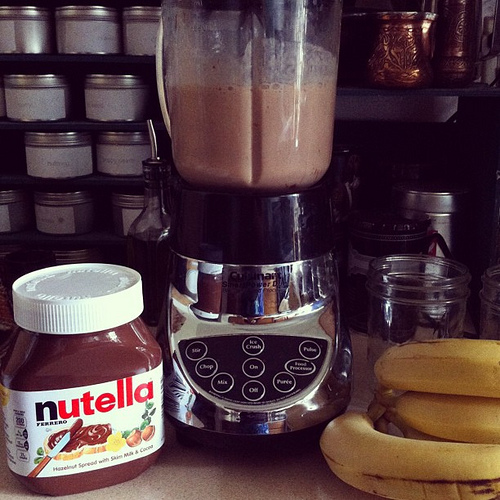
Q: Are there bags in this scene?
A: No, there are no bags.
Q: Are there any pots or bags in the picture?
A: No, there are no bags or pots.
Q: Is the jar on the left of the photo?
A: Yes, the jar is on the left of the image.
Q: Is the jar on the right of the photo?
A: No, the jar is on the left of the image.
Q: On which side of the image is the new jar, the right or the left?
A: The jar is on the left of the image.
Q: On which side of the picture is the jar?
A: The jar is on the left of the image.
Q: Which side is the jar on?
A: The jar is on the left of the image.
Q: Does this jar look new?
A: Yes, the jar is new.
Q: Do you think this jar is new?
A: Yes, the jar is new.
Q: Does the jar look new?
A: Yes, the jar is new.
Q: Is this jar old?
A: No, the jar is new.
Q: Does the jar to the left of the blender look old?
A: No, the jar is new.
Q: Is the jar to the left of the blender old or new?
A: The jar is new.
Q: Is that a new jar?
A: Yes, that is a new jar.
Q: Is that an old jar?
A: No, that is a new jar.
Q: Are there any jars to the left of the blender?
A: Yes, there is a jar to the left of the blender.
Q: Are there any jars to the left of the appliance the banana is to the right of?
A: Yes, there is a jar to the left of the blender.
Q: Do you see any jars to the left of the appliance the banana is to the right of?
A: Yes, there is a jar to the left of the blender.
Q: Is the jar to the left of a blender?
A: Yes, the jar is to the left of a blender.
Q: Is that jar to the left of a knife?
A: No, the jar is to the left of a blender.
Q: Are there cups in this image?
A: No, there are no cups.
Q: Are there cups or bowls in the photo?
A: No, there are no cups or bowls.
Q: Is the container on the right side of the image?
A: No, the container is on the left of the image.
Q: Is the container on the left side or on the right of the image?
A: The container is on the left of the image.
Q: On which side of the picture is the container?
A: The container is on the left of the image.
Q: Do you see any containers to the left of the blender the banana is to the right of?
A: Yes, there is a container to the left of the blender.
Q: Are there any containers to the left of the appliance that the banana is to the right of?
A: Yes, there is a container to the left of the blender.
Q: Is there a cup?
A: No, there are no cups.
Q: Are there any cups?
A: No, there are no cups.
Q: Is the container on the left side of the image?
A: Yes, the container is on the left of the image.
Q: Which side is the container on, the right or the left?
A: The container is on the left of the image.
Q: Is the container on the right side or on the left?
A: The container is on the left of the image.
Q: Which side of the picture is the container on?
A: The container is on the left of the image.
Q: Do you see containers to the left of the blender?
A: Yes, there is a container to the left of the blender.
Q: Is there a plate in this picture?
A: No, there are no plates.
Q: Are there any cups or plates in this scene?
A: No, there are no plates or cups.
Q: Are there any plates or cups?
A: No, there are no plates or cups.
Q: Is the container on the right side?
A: No, the container is on the left of the image.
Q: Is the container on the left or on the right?
A: The container is on the left of the image.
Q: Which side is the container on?
A: The container is on the left of the image.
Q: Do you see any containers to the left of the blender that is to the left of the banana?
A: Yes, there is a container to the left of the blender.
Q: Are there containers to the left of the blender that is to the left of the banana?
A: Yes, there is a container to the left of the blender.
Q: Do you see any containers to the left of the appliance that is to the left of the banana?
A: Yes, there is a container to the left of the blender.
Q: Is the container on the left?
A: Yes, the container is on the left of the image.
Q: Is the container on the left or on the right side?
A: The container is on the left of the image.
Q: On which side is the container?
A: The container is on the left of the image.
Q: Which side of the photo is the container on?
A: The container is on the left of the image.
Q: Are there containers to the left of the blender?
A: Yes, there is a container to the left of the blender.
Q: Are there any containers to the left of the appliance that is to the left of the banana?
A: Yes, there is a container to the left of the blender.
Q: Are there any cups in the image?
A: No, there are no cups.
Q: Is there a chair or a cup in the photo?
A: No, there are no cups or chairs.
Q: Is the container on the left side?
A: Yes, the container is on the left of the image.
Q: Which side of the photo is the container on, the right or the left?
A: The container is on the left of the image.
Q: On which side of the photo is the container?
A: The container is on the left of the image.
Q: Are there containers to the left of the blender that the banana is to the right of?
A: Yes, there is a container to the left of the blender.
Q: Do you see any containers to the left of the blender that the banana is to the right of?
A: Yes, there is a container to the left of the blender.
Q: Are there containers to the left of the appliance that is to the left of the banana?
A: Yes, there is a container to the left of the blender.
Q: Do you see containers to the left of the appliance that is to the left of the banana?
A: Yes, there is a container to the left of the blender.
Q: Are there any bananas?
A: Yes, there is a banana.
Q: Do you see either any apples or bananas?
A: Yes, there is a banana.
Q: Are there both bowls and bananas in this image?
A: No, there is a banana but no bowls.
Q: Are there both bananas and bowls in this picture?
A: No, there is a banana but no bowls.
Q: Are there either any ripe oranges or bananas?
A: Yes, there is a ripe banana.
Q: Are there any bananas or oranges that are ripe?
A: Yes, the banana is ripe.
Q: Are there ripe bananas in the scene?
A: Yes, there is a ripe banana.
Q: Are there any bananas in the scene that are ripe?
A: Yes, there is a banana that is ripe.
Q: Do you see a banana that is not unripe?
A: Yes, there is an ripe banana.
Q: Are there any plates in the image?
A: No, there are no plates.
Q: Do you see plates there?
A: No, there are no plates.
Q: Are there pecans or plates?
A: No, there are no plates or pecans.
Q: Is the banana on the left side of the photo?
A: No, the banana is on the right of the image.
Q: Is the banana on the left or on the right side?
A: The banana is on the right of the image.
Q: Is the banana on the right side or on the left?
A: The banana is on the right of the image.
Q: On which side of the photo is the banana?
A: The banana is on the right of the image.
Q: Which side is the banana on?
A: The banana is on the right of the image.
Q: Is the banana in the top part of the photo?
A: No, the banana is in the bottom of the image.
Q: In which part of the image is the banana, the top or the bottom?
A: The banana is in the bottom of the image.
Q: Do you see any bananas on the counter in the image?
A: Yes, there is a banana on the counter.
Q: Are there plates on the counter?
A: No, there is a banana on the counter.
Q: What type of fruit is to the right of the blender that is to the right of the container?
A: The fruit is a banana.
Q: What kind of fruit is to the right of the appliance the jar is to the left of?
A: The fruit is a banana.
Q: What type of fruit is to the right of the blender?
A: The fruit is a banana.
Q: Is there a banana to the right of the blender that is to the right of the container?
A: Yes, there is a banana to the right of the blender.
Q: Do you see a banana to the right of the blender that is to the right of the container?
A: Yes, there is a banana to the right of the blender.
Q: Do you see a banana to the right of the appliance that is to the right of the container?
A: Yes, there is a banana to the right of the blender.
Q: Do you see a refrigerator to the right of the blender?
A: No, there is a banana to the right of the blender.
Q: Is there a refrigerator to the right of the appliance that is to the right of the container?
A: No, there is a banana to the right of the blender.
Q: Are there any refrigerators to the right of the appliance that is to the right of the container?
A: No, there is a banana to the right of the blender.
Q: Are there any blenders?
A: Yes, there is a blender.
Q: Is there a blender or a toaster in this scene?
A: Yes, there is a blender.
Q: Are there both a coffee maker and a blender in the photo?
A: No, there is a blender but no coffee makers.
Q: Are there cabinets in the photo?
A: No, there are no cabinets.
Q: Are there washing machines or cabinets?
A: No, there are no cabinets or washing machines.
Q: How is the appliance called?
A: The appliance is a blender.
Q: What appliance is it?
A: The appliance is a blender.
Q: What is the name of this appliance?
A: This is a blender.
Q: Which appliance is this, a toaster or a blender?
A: This is a blender.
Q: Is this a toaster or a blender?
A: This is a blender.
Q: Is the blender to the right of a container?
A: Yes, the blender is to the right of a container.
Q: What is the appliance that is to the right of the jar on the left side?
A: The appliance is a blender.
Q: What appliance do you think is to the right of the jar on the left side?
A: The appliance is a blender.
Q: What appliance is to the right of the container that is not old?
A: The appliance is a blender.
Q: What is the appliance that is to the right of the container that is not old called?
A: The appliance is a blender.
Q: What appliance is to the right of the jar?
A: The appliance is a blender.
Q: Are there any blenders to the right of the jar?
A: Yes, there is a blender to the right of the jar.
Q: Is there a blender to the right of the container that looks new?
A: Yes, there is a blender to the right of the jar.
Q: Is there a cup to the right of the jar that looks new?
A: No, there is a blender to the right of the jar.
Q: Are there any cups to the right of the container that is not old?
A: No, there is a blender to the right of the jar.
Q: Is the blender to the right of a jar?
A: Yes, the blender is to the right of a jar.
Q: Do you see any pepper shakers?
A: No, there are no pepper shakers.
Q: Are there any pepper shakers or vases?
A: No, there are no pepper shakers or vases.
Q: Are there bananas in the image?
A: Yes, there is a banana.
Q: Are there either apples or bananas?
A: Yes, there is a banana.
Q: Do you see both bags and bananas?
A: No, there is a banana but no bags.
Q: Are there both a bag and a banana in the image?
A: No, there is a banana but no bags.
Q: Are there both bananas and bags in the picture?
A: No, there is a banana but no bags.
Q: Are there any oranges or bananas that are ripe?
A: Yes, the banana is ripe.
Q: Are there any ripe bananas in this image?
A: Yes, there is a ripe banana.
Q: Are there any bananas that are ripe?
A: Yes, there is a banana that is ripe.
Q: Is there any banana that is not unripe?
A: Yes, there is an ripe banana.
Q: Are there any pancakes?
A: No, there are no pancakes.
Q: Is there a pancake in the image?
A: No, there are no pancakes.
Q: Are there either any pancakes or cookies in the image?
A: No, there are no pancakes or cookies.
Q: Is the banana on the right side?
A: Yes, the banana is on the right of the image.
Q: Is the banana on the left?
A: No, the banana is on the right of the image.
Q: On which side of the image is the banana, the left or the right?
A: The banana is on the right of the image.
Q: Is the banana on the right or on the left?
A: The banana is on the right of the image.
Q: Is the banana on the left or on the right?
A: The banana is on the right of the image.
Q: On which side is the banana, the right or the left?
A: The banana is on the right of the image.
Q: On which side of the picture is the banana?
A: The banana is on the right of the image.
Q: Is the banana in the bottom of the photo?
A: Yes, the banana is in the bottom of the image.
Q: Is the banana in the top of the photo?
A: No, the banana is in the bottom of the image.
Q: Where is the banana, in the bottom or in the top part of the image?
A: The banana is in the bottom of the image.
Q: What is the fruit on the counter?
A: The fruit is a banana.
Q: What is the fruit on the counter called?
A: The fruit is a banana.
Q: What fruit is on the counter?
A: The fruit is a banana.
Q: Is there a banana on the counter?
A: Yes, there is a banana on the counter.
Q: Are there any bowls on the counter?
A: No, there is a banana on the counter.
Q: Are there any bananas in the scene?
A: Yes, there is a banana.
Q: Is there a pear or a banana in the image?
A: Yes, there is a banana.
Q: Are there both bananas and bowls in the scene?
A: No, there is a banana but no bowls.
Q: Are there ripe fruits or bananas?
A: Yes, there is a ripe banana.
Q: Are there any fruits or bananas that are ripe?
A: Yes, the banana is ripe.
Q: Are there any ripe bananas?
A: Yes, there is a ripe banana.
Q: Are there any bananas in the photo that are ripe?
A: Yes, there is a banana that is ripe.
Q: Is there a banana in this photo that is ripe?
A: Yes, there is a banana that is ripe.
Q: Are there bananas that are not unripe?
A: Yes, there is an ripe banana.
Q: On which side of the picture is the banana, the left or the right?
A: The banana is on the right of the image.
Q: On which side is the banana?
A: The banana is on the right of the image.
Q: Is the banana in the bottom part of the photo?
A: Yes, the banana is in the bottom of the image.